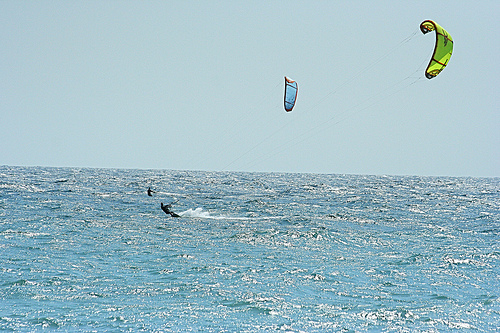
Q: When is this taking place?
A: Daytime.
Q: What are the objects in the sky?
A: Sails.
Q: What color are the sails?
A: Green and blue.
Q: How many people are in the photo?
A: Two.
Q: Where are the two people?
A: Body of water.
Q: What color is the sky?
A: Blue.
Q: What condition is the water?
A: Calm.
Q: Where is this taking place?
A: At the ocean.